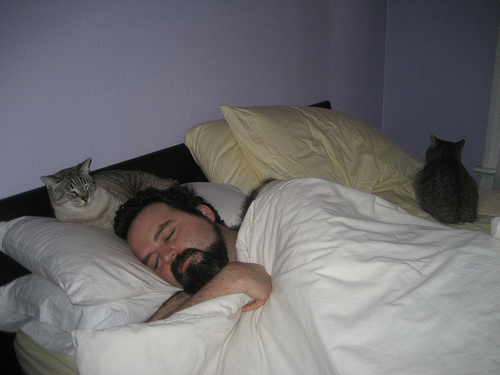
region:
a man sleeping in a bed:
[113, 180, 270, 322]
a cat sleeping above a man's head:
[40, 157, 176, 234]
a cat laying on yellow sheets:
[413, 135, 480, 223]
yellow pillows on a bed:
[183, 105, 423, 214]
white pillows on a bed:
[2, 180, 248, 336]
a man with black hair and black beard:
[113, 178, 228, 296]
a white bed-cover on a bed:
[73, 176, 496, 373]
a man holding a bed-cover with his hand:
[221, 263, 273, 318]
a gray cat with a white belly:
[38, 157, 179, 232]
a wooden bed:
[0, 98, 334, 373]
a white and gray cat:
[42, 160, 176, 225]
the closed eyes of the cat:
[67, 182, 91, 195]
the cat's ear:
[77, 156, 94, 173]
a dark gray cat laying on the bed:
[412, 132, 473, 224]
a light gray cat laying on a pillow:
[44, 157, 171, 225]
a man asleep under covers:
[113, 182, 498, 373]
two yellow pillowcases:
[183, 111, 415, 189]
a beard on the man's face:
[173, 243, 226, 291]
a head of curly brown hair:
[107, 182, 214, 234]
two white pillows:
[9, 182, 241, 334]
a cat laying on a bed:
[384, 126, 484, 240]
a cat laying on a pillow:
[41, 148, 155, 235]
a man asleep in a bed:
[78, 181, 415, 368]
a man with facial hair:
[157, 221, 228, 300]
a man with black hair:
[104, 179, 220, 244]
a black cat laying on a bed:
[398, 131, 473, 231]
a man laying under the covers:
[176, 164, 338, 326]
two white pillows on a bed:
[5, 237, 104, 372]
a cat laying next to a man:
[60, 150, 185, 253]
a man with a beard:
[152, 228, 230, 318]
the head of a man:
[111, 181, 231, 290]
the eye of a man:
[158, 226, 179, 243]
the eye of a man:
[145, 254, 164, 271]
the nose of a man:
[155, 244, 173, 262]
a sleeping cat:
[32, 152, 159, 217]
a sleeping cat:
[412, 129, 482, 225]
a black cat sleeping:
[412, 132, 487, 233]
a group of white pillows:
[1, 212, 145, 333]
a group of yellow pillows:
[188, 101, 419, 204]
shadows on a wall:
[268, 2, 488, 124]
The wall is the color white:
[16, 6, 401, 99]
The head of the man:
[108, 178, 230, 305]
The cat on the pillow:
[40, 153, 187, 235]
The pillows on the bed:
[211, 105, 398, 184]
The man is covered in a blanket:
[88, 174, 497, 366]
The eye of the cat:
[62, 181, 81, 199]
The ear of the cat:
[35, 172, 64, 192]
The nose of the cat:
[76, 188, 93, 205]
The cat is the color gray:
[409, 120, 484, 225]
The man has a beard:
[166, 236, 230, 296]